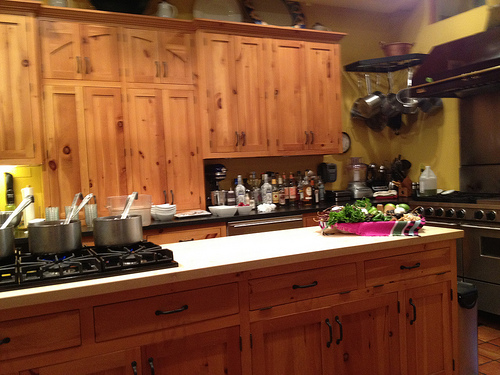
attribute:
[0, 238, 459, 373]
kitchen cabinets — wooden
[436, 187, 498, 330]
stove — steel 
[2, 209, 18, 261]
pot — silver 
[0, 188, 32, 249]
pot — silver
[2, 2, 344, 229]
cabinets — natural, wood, light-colored, wooden, kitchen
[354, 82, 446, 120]
pots — metal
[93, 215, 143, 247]
pot — steel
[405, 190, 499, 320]
stove — stainless 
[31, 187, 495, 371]
cabinets — white 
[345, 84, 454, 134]
pots — metal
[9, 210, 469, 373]
counter top — white 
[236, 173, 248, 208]
bottle — glass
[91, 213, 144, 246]
pot — silver 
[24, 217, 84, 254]
pot — silver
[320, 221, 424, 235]
tray — pink 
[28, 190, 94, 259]
pot — stainless, steel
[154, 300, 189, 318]
handle — black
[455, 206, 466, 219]
knob — black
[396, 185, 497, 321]
stove — stainless, steel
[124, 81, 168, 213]
cabinet — closed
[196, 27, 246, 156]
cabinet — closed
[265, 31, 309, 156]
cabinet — closed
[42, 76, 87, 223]
cabinet — closed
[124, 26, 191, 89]
cabinet — closed